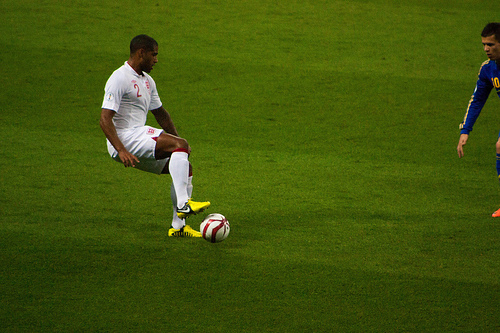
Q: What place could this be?
A: It is a field.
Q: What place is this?
A: It is a field.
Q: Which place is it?
A: It is a field.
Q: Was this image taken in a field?
A: Yes, it was taken in a field.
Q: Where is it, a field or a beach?
A: It is a field.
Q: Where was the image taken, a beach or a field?
A: It was taken at a field.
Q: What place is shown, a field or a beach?
A: It is a field.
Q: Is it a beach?
A: No, it is a field.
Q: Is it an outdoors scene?
A: Yes, it is outdoors.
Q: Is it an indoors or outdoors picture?
A: It is outdoors.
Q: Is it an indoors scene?
A: No, it is outdoors.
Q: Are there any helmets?
A: No, there are no helmets.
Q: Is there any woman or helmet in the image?
A: No, there are no helmets or women.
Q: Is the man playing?
A: Yes, the man is playing.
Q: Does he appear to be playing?
A: Yes, the man is playing.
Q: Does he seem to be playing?
A: Yes, the man is playing.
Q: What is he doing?
A: The man is playing.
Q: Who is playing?
A: The man is playing.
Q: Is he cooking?
A: No, the man is playing.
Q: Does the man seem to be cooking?
A: No, the man is playing.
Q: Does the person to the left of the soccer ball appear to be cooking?
A: No, the man is playing.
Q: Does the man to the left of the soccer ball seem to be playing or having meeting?
A: The man is playing.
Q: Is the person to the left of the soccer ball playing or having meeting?
A: The man is playing.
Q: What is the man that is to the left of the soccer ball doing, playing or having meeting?
A: The man is playing.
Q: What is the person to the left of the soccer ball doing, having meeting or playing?
A: The man is playing.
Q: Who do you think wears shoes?
A: The man wears shoes.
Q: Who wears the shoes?
A: The man wears shoes.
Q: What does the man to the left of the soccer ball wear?
A: The man wears shoes.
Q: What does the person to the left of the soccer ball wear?
A: The man wears shoes.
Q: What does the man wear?
A: The man wears shoes.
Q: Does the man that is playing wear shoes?
A: Yes, the man wears shoes.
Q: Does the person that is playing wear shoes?
A: Yes, the man wears shoes.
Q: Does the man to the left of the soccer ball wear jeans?
A: No, the man wears shoes.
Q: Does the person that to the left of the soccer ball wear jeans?
A: No, the man wears shoes.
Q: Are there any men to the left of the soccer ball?
A: Yes, there is a man to the left of the soccer ball.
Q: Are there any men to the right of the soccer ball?
A: No, the man is to the left of the soccer ball.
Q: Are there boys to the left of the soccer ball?
A: No, there is a man to the left of the soccer ball.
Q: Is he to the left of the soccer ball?
A: Yes, the man is to the left of the soccer ball.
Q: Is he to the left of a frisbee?
A: No, the man is to the left of the soccer ball.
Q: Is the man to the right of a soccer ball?
A: No, the man is to the left of a soccer ball.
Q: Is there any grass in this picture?
A: Yes, there is grass.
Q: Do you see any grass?
A: Yes, there is grass.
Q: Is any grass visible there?
A: Yes, there is grass.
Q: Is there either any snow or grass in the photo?
A: Yes, there is grass.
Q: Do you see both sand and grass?
A: No, there is grass but no sand.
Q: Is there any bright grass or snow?
A: Yes, there is bright grass.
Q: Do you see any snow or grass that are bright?
A: Yes, the grass is bright.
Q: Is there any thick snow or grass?
A: Yes, there is thick grass.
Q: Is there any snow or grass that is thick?
A: Yes, the grass is thick.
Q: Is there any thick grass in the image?
A: Yes, there is thick grass.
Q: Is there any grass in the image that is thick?
A: Yes, there is grass that is thick.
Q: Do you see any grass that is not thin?
A: Yes, there is thick grass.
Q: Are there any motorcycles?
A: No, there are no motorcycles.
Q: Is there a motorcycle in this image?
A: No, there are no motorcycles.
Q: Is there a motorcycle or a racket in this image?
A: No, there are no motorcycles or rackets.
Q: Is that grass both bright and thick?
A: Yes, the grass is bright and thick.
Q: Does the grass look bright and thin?
A: No, the grass is bright but thick.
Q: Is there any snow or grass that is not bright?
A: No, there is grass but it is bright.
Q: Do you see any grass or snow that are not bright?
A: No, there is grass but it is bright.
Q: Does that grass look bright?
A: Yes, the grass is bright.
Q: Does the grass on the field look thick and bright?
A: Yes, the grass is thick and bright.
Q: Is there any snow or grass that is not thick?
A: No, there is grass but it is thick.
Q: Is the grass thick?
A: Yes, the grass is thick.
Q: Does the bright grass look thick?
A: Yes, the grass is thick.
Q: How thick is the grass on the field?
A: The grass is thick.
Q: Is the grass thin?
A: No, the grass is thick.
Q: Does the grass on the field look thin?
A: No, the grass is thick.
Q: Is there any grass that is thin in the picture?
A: No, there is grass but it is thick.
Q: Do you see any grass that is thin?
A: No, there is grass but it is thick.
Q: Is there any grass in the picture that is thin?
A: No, there is grass but it is thick.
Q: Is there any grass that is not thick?
A: No, there is grass but it is thick.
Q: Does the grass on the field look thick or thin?
A: The grass is thick.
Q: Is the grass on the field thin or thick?
A: The grass is thick.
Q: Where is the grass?
A: The grass is on the field.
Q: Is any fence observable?
A: No, there are no fences.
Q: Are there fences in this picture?
A: No, there are no fences.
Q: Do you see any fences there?
A: No, there are no fences.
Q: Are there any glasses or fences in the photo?
A: No, there are no fences or glasses.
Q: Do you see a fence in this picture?
A: No, there are no fences.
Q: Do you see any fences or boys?
A: No, there are no fences or boys.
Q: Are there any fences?
A: No, there are no fences.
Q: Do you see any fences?
A: No, there are no fences.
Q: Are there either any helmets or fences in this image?
A: No, there are no fences or helmets.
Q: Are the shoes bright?
A: Yes, the shoes are bright.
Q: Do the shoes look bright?
A: Yes, the shoes are bright.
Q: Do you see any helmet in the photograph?
A: No, there are no helmets.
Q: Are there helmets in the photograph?
A: No, there are no helmets.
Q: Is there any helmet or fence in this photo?
A: No, there are no helmets or fences.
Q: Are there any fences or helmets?
A: No, there are no helmets or fences.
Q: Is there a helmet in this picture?
A: No, there are no helmets.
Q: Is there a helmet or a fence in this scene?
A: No, there are no helmets or fences.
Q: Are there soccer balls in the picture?
A: Yes, there is a soccer ball.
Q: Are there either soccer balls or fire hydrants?
A: Yes, there is a soccer ball.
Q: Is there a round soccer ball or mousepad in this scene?
A: Yes, there is a round soccer ball.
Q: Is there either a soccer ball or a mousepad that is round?
A: Yes, the soccer ball is round.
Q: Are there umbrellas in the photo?
A: No, there are no umbrellas.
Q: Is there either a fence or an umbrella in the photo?
A: No, there are no umbrellas or fences.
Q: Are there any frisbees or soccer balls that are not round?
A: No, there is a soccer ball but it is round.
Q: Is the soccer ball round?
A: Yes, the soccer ball is round.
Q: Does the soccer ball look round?
A: Yes, the soccer ball is round.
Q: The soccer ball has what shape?
A: The soccer ball is round.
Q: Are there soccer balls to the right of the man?
A: Yes, there is a soccer ball to the right of the man.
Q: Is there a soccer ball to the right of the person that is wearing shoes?
A: Yes, there is a soccer ball to the right of the man.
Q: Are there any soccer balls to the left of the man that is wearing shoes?
A: No, the soccer ball is to the right of the man.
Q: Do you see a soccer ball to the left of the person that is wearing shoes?
A: No, the soccer ball is to the right of the man.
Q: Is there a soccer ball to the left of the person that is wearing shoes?
A: No, the soccer ball is to the right of the man.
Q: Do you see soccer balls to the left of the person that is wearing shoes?
A: No, the soccer ball is to the right of the man.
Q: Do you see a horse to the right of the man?
A: No, there is a soccer ball to the right of the man.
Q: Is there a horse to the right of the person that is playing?
A: No, there is a soccer ball to the right of the man.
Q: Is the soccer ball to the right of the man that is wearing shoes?
A: Yes, the soccer ball is to the right of the man.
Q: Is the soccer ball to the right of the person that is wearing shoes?
A: Yes, the soccer ball is to the right of the man.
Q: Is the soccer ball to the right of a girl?
A: No, the soccer ball is to the right of the man.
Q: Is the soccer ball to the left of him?
A: No, the soccer ball is to the right of a man.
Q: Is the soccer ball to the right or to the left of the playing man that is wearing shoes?
A: The soccer ball is to the right of the man.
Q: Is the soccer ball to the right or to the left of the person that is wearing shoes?
A: The soccer ball is to the right of the man.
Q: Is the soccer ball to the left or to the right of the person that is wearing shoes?
A: The soccer ball is to the right of the man.